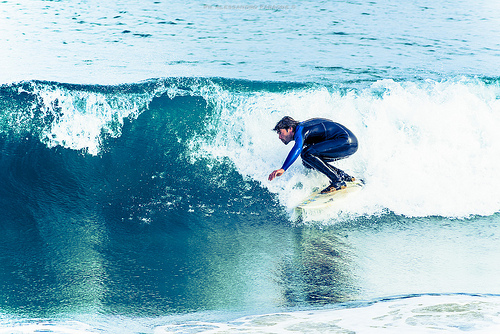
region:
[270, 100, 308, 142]
head of a person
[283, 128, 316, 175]
arm of a person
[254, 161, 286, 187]
hand of a person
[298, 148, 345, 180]
leg of a person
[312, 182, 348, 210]
feet of a person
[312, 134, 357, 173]
thigh of a person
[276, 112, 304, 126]
hair of a person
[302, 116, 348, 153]
body of a person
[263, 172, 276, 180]
finger of a person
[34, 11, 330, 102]
a body of water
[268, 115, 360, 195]
person in dark blue wet suit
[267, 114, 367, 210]
person balancing on beige surfboard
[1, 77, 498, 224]
person surfing wave in ocean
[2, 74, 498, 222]
ocean wave is white at the crest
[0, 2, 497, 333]
water is beautiful turquoise blue color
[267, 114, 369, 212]
person surfing is leaning over the board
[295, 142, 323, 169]
person has knees bent while surfing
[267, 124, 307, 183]
left arm is forward to help with balance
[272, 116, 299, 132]
person has collar length dark hair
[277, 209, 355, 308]
person's reflection is mirrored in the ocean water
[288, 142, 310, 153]
elbow of a person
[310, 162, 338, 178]
leg of a person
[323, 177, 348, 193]
feet of a person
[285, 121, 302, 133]
ear of a person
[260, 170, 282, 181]
finger of a person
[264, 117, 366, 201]
Surfer in a blue suit.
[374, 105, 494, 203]
White foam on water waves.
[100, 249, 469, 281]
Sky and surfer reflections on the water.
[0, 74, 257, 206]
A large surfer's blue wave.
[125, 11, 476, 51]
Waves on the open ocean.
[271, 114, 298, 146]
The head of a man.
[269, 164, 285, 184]
The hand of a surfer.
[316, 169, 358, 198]
The feet of a surfer.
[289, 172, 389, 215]
A surfer's surfboard on the water.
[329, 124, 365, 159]
Sunlight bouncing off a surfer's butt.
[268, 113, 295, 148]
head of a person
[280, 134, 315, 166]
arm of a person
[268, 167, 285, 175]
hand of a person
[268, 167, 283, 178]
finger of a person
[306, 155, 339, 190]
leg of a person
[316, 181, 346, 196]
feet of a person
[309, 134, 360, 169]
thigh of a person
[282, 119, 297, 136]
ear of a person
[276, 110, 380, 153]
body of a person